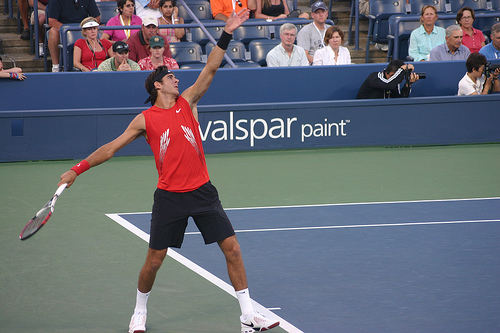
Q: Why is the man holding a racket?
A: Tennis.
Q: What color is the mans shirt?
A: Red.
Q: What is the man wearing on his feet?
A: Sneakers.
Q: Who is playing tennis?
A: Man.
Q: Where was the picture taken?
A: Tennis court.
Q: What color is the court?
A: Green.